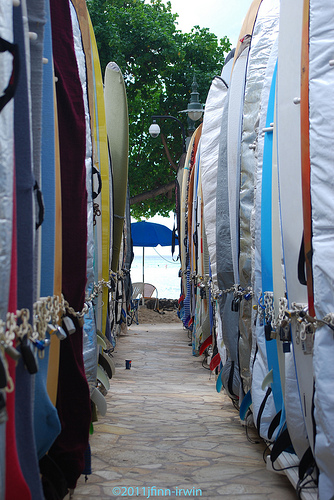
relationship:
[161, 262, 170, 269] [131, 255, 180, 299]
person in water